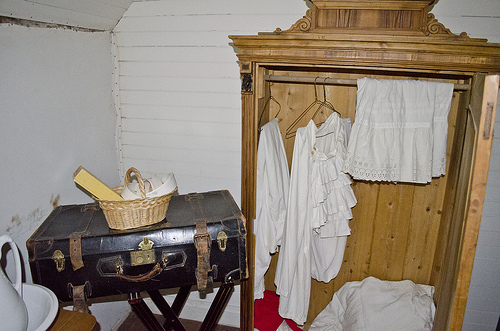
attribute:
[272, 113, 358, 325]
shirt — white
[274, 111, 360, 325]
clothes item — white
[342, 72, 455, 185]
clothes item — white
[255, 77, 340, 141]
hangers — metal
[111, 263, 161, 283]
handle — brown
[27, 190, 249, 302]
suitcase — black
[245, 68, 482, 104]
pole — wooden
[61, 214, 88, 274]
strap — brown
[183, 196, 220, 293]
strap — brown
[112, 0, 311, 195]
wall — white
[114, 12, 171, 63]
board — white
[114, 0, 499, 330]
brick wall — white, painted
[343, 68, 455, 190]
cloth — white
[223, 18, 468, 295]
wood cabinet — pale brown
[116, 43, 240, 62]
board — white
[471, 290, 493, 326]
board — white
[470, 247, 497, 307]
wall — white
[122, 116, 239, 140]
board — white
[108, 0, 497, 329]
wall — white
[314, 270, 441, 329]
blanket — partially-folded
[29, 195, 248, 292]
suitcase — black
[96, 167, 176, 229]
basket — light, brown, woven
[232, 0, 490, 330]
closet — light, color, wooden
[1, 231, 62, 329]
basin — wash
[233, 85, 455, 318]
linens — white